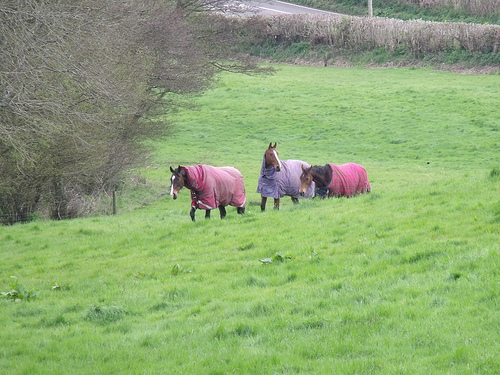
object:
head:
[170, 165, 187, 200]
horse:
[169, 164, 247, 222]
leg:
[190, 208, 197, 221]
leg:
[205, 210, 210, 219]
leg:
[218, 206, 226, 220]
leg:
[261, 197, 268, 211]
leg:
[274, 198, 279, 209]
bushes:
[414, 26, 499, 61]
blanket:
[186, 165, 245, 210]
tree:
[0, 0, 173, 229]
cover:
[326, 163, 370, 197]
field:
[0, 56, 500, 375]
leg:
[236, 207, 244, 214]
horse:
[256, 142, 317, 210]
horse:
[299, 163, 370, 198]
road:
[185, 0, 337, 16]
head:
[299, 164, 313, 195]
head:
[264, 142, 280, 171]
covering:
[256, 153, 315, 200]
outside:
[0, 0, 499, 372]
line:
[228, 0, 291, 14]